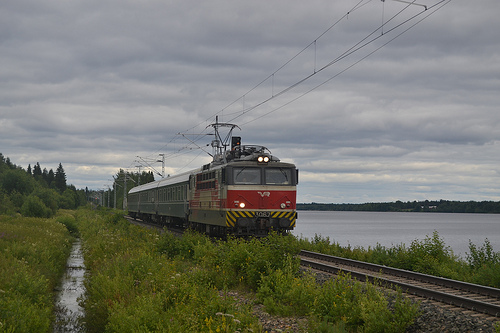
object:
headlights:
[279, 201, 288, 210]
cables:
[121, 111, 224, 182]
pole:
[113, 180, 118, 210]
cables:
[223, 0, 478, 126]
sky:
[0, 0, 497, 199]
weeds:
[0, 205, 499, 332]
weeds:
[283, 230, 498, 293]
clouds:
[0, 0, 499, 205]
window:
[261, 167, 293, 186]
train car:
[187, 160, 298, 237]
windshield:
[232, 163, 264, 186]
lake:
[316, 213, 498, 276]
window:
[232, 163, 264, 185]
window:
[180, 184, 188, 200]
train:
[124, 143, 300, 242]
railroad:
[117, 214, 499, 330]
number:
[258, 188, 270, 200]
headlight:
[238, 201, 245, 208]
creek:
[53, 227, 92, 329]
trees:
[16, 159, 92, 215]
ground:
[4, 244, 470, 304]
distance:
[2, 159, 175, 194]